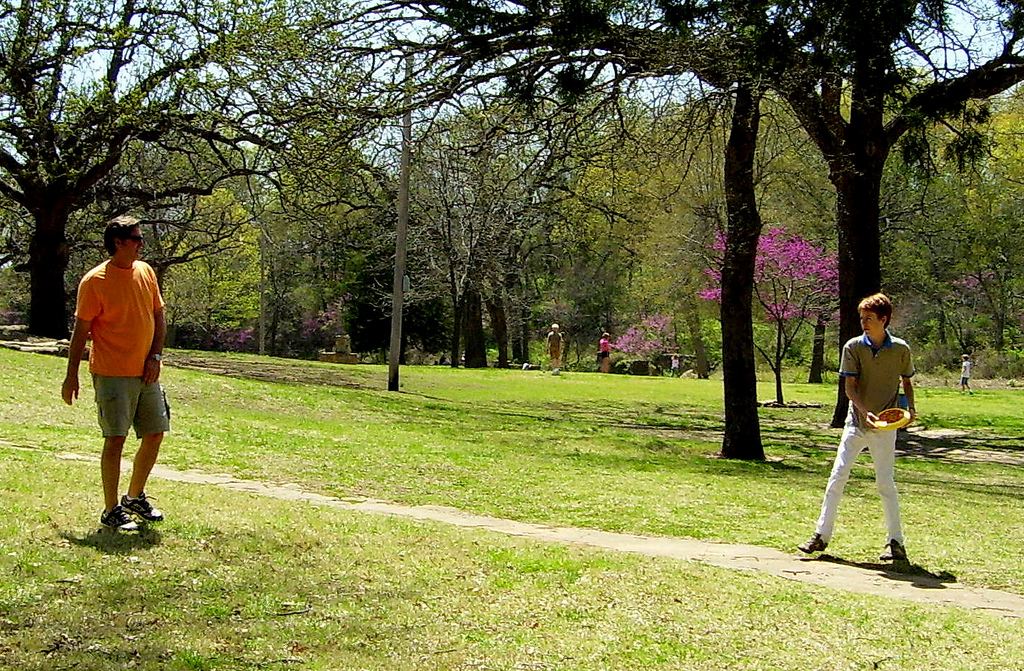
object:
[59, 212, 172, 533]
man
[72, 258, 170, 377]
shirt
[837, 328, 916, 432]
shirt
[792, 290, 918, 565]
boy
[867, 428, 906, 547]
pants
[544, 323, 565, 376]
person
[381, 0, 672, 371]
tree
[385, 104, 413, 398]
pole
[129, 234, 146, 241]
sunglasses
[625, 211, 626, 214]
leaves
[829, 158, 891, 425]
trunk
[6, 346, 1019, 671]
grass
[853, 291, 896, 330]
hair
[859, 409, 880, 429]
hand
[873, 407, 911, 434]
frisbee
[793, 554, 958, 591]
shadow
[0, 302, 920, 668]
ground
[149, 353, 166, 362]
watch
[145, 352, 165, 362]
wrist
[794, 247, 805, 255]
flowers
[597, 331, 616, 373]
person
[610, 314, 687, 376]
bush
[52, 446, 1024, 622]
path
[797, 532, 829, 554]
foot